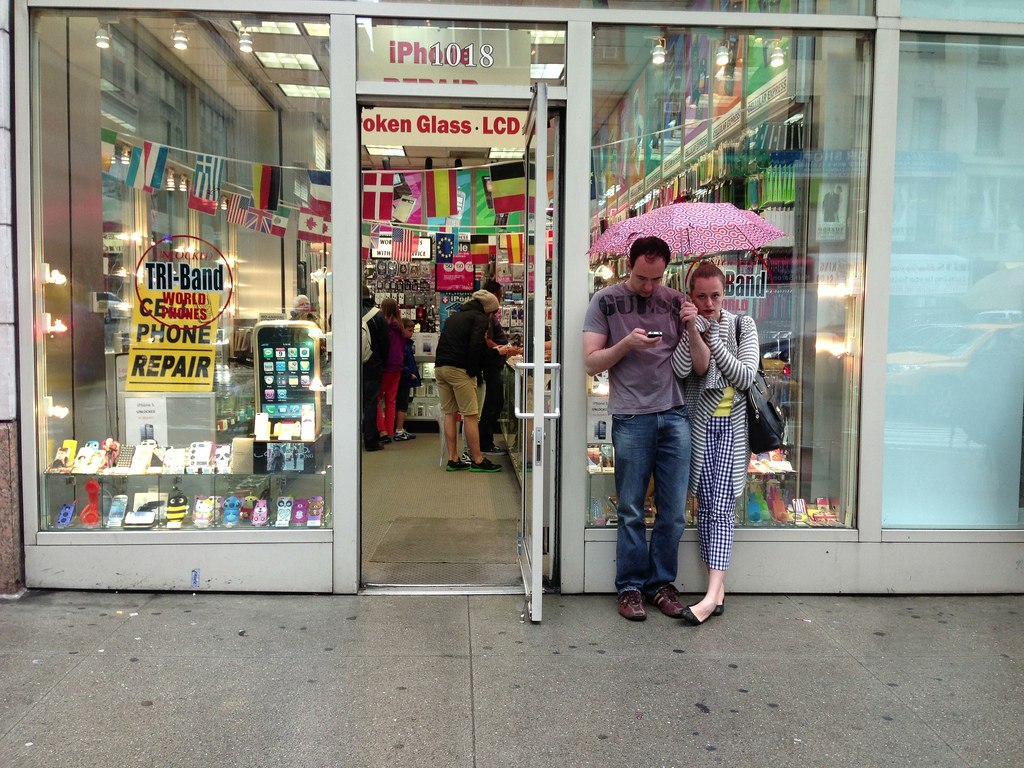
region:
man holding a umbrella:
[591, 190, 770, 271]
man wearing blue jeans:
[599, 401, 689, 583]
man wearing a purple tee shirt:
[584, 284, 683, 411]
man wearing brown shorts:
[424, 353, 483, 415]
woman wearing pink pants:
[370, 366, 405, 430]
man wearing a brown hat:
[470, 282, 505, 312]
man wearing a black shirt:
[408, 294, 495, 374]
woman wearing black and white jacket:
[680, 309, 778, 499]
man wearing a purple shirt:
[581, 281, 679, 414]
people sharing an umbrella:
[582, 200, 769, 630]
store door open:
[509, 79, 564, 631]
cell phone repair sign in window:
[123, 281, 219, 398]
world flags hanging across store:
[95, 121, 788, 223]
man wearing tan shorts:
[432, 293, 506, 478]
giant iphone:
[247, 319, 323, 440]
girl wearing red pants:
[379, 296, 409, 451]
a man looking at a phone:
[579, 253, 697, 626]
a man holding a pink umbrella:
[611, 186, 749, 624]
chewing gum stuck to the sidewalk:
[544, 648, 833, 750]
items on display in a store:
[45, 427, 339, 535]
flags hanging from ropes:
[121, 127, 704, 246]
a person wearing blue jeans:
[608, 411, 691, 595]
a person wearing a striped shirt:
[683, 304, 772, 394]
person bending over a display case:
[427, 285, 514, 475]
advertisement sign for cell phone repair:
[122, 285, 224, 396]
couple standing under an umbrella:
[578, 196, 795, 631]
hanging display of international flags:
[127, 118, 634, 267]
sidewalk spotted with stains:
[2, 586, 1021, 765]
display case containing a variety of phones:
[41, 433, 332, 532]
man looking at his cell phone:
[578, 231, 715, 628]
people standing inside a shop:
[359, 280, 421, 454]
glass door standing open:
[511, 77, 565, 629]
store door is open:
[354, 62, 563, 621]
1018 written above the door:
[425, 31, 504, 69]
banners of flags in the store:
[87, 110, 557, 267]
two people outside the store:
[539, 208, 824, 427]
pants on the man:
[543, 405, 728, 586]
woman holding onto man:
[540, 253, 817, 511]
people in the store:
[280, 279, 556, 453]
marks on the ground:
[676, 636, 806, 742]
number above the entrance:
[382, 25, 526, 102]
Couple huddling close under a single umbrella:
[574, 190, 806, 628]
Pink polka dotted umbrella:
[585, 186, 788, 333]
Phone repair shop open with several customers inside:
[5, 0, 882, 623]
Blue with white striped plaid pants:
[684, 413, 751, 573]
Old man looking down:
[427, 281, 514, 482]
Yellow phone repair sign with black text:
[115, 272, 229, 397]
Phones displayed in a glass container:
[35, 417, 343, 544]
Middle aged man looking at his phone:
[573, 233, 730, 641]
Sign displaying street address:
[337, 10, 578, 87]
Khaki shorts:
[422, 357, 496, 427]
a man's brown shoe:
[610, 590, 649, 623]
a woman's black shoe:
[675, 591, 713, 627]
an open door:
[497, 73, 565, 611]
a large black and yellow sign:
[117, 279, 231, 396]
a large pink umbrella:
[590, 196, 783, 261]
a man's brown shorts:
[434, 356, 492, 415]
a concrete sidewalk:
[1, 581, 1020, 765]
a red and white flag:
[356, 168, 395, 223]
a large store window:
[599, 25, 860, 510]